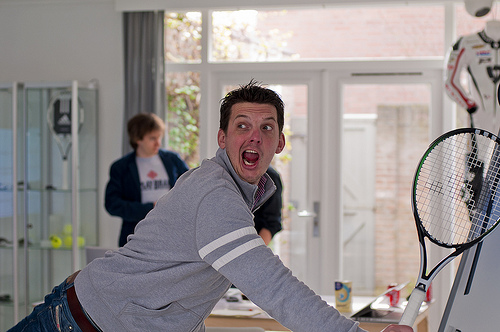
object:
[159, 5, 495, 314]
window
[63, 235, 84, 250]
tennis balls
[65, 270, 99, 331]
belt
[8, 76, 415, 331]
man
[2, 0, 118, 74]
wall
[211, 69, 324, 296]
glass doors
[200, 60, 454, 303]
white frames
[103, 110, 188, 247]
hipster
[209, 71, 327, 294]
doorway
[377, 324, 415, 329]
hand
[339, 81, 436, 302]
large glass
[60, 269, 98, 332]
waist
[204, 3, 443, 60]
large window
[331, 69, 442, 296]
doorway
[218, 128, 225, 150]
human rear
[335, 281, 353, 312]
carton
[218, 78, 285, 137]
dark hair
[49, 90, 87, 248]
items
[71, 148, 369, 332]
gray shirt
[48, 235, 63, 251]
tennis balls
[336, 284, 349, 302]
blue swirl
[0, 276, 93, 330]
man's pants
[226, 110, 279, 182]
man's face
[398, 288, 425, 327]
grip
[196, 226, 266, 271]
stripe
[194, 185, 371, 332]
sleeve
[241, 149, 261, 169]
mouth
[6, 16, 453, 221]
background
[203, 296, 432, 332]
counter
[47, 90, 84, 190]
racket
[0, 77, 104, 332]
case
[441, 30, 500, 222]
outfit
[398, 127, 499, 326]
racket